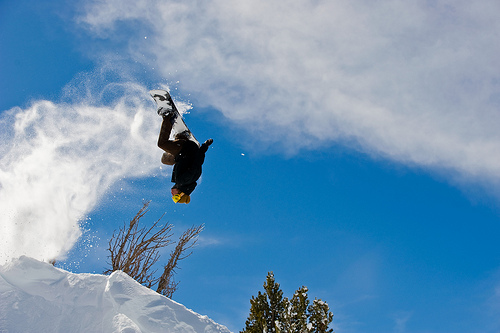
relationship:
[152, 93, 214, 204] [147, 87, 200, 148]
person on snowboard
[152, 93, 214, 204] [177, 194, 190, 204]
person wearing hat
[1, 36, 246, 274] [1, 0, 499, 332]
snow in air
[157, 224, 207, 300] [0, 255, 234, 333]
weed behind snowbank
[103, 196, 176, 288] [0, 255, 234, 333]
weed behind snowbank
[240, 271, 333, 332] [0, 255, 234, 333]
tree behind snowbank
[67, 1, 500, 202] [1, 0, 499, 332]
cloud in air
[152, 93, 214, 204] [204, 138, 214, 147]
person wearing glove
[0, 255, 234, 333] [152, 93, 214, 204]
snowbank under person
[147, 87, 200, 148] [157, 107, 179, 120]
snowboard attached to foot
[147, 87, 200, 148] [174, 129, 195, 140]
snowboard attached to foot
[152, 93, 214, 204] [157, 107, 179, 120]
person has foot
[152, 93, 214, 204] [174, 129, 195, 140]
person has foot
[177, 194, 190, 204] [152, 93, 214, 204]
hat on person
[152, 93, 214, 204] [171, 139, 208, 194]
person wearing jacket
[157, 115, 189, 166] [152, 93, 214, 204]
pants on person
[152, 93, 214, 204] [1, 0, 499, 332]
person in air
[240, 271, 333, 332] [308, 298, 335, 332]
tree has branch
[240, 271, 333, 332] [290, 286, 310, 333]
tree has branch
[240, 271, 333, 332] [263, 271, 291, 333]
tree has branch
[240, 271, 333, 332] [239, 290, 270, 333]
tree has branch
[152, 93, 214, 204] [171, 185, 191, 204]
person has head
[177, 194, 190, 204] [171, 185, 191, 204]
hat on head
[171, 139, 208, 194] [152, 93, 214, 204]
jacket on person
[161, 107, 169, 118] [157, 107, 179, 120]
snow on snow boot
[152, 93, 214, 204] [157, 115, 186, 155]
person has leg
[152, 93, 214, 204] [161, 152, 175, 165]
person has leg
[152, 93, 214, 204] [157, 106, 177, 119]
person has shoe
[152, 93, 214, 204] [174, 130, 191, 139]
person has shoe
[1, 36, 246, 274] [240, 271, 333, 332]
snow on tree